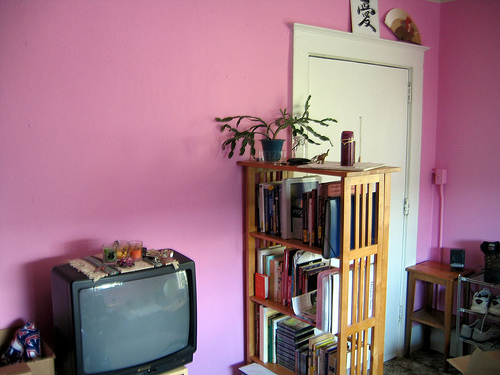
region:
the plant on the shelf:
[214, 95, 336, 165]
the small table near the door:
[402, 259, 469, 369]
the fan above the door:
[384, 6, 422, 45]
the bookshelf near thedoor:
[237, 160, 400, 373]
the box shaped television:
[49, 248, 196, 373]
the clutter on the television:
[62, 239, 179, 281]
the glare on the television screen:
[77, 269, 192, 371]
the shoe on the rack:
[470, 287, 488, 313]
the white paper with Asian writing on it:
[350, 0, 380, 36]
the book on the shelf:
[257, 180, 264, 233]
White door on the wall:
[305, 52, 410, 372]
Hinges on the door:
[397, 76, 412, 319]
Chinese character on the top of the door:
[352, 1, 378, 32]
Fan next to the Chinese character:
[382, 5, 422, 42]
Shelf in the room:
[237, 156, 402, 373]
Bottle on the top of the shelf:
[339, 129, 357, 166]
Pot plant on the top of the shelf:
[213, 95, 338, 162]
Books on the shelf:
[251, 171, 341, 373]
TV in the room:
[48, 247, 197, 373]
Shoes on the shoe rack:
[459, 237, 497, 339]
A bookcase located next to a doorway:
[211, 128, 396, 373]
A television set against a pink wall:
[37, 238, 206, 373]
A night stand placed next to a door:
[403, 242, 464, 357]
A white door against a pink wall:
[280, 20, 425, 369]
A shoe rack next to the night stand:
[455, 266, 498, 373]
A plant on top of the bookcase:
[197, 110, 327, 166]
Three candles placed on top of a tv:
[96, 239, 160, 263]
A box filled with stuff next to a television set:
[1, 321, 55, 374]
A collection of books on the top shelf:
[257, 175, 349, 255]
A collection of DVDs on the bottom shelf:
[275, 316, 321, 373]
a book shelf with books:
[246, 156, 393, 372]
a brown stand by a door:
[398, 259, 460, 359]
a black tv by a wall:
[53, 248, 203, 370]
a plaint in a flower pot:
[217, 89, 338, 157]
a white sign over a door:
[349, 1, 381, 33]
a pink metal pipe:
[429, 166, 454, 241]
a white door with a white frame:
[289, 15, 430, 140]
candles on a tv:
[77, 233, 176, 278]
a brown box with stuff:
[2, 319, 57, 374]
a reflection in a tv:
[98, 274, 199, 363]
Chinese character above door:
[350, 0, 384, 37]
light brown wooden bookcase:
[239, 153, 401, 373]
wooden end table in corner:
[401, 253, 487, 363]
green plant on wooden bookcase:
[208, 93, 340, 167]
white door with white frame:
[291, 20, 432, 360]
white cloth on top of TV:
[60, 244, 181, 279]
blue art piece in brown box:
[1, 318, 60, 373]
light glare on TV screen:
[86, 270, 193, 297]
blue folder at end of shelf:
[325, 190, 384, 257]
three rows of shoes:
[448, 236, 498, 365]